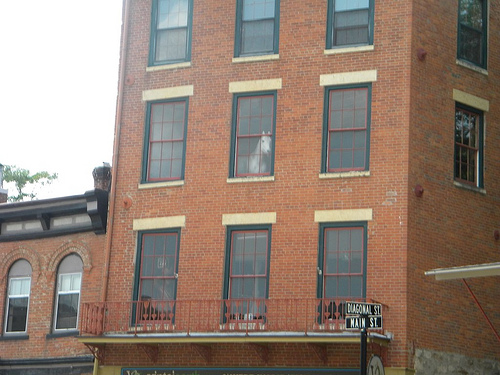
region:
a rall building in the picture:
[144, 47, 497, 337]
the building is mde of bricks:
[134, 72, 427, 372]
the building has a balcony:
[86, 283, 338, 340]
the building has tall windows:
[153, 99, 358, 306]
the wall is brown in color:
[385, 143, 434, 350]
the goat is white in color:
[252, 127, 317, 202]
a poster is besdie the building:
[337, 300, 407, 372]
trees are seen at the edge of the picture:
[1, 154, 64, 209]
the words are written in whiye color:
[349, 296, 391, 336]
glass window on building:
[316, 227, 363, 318]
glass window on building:
[227, 228, 265, 318]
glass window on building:
[137, 233, 175, 320]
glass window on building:
[319, 83, 370, 171]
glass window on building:
[231, 90, 276, 180]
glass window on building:
[141, 97, 186, 181]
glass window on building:
[326, 0, 372, 51]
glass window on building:
[237, 0, 277, 55]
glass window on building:
[151, 2, 188, 62]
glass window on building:
[53, 273, 80, 335]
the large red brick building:
[1, 2, 498, 374]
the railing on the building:
[80, 297, 387, 333]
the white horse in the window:
[236, 130, 271, 172]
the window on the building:
[229, 90, 276, 175]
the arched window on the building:
[51, 251, 84, 329]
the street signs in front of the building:
[345, 301, 383, 329]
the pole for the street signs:
[360, 330, 366, 374]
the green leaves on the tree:
[0, 163, 58, 203]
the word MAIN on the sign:
[348, 317, 365, 327]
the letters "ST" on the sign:
[369, 316, 376, 326]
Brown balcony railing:
[75, 293, 385, 335]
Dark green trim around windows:
[229, 91, 277, 178]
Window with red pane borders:
[233, 95, 271, 178]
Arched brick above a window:
[45, 239, 91, 274]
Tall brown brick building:
[75, 0, 497, 374]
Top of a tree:
[1, 160, 58, 203]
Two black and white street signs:
[340, 300, 382, 331]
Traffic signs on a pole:
[343, 299, 386, 373]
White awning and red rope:
[422, 258, 497, 349]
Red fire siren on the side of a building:
[413, 45, 430, 64]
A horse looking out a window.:
[230, 82, 280, 179]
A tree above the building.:
[1, 160, 65, 205]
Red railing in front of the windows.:
[77, 295, 352, 347]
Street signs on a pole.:
[339, 293, 392, 335]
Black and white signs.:
[339, 298, 388, 338]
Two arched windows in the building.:
[4, 240, 88, 353]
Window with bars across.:
[444, 90, 492, 197]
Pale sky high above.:
[17, 48, 91, 131]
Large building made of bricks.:
[383, 205, 472, 284]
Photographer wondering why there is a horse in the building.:
[225, 84, 290, 188]